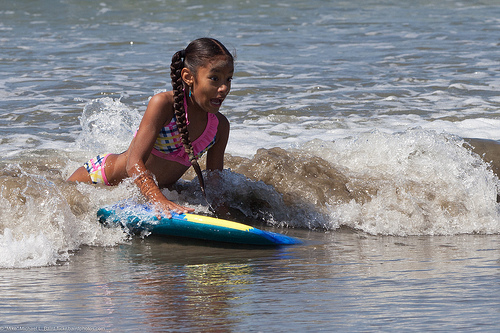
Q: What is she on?
A: Board.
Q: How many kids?
A: 1.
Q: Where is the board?
A: On the water.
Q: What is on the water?
A: The girl.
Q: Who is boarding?
A: The girl.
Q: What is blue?
A: Water.